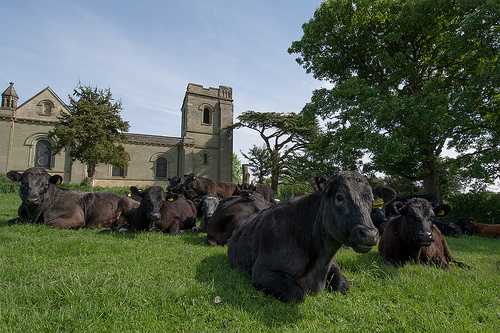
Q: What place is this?
A: It is a field.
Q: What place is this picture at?
A: It is at the field.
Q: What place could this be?
A: It is a field.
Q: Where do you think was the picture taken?
A: It was taken at the field.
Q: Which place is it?
A: It is a field.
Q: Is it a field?
A: Yes, it is a field.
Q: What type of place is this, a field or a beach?
A: It is a field.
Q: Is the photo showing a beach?
A: No, the picture is showing a field.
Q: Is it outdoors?
A: Yes, it is outdoors.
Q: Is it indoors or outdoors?
A: It is outdoors.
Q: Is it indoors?
A: No, it is outdoors.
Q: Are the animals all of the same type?
A: Yes, all the animals are cows.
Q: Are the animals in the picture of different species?
A: No, all the animals are cows.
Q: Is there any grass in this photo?
A: Yes, there is grass.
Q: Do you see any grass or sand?
A: Yes, there is grass.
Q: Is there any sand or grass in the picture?
A: Yes, there is grass.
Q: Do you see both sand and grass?
A: No, there is grass but no sand.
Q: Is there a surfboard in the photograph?
A: No, there are no surfboards.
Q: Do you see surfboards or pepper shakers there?
A: No, there are no surfboards or pepper shakers.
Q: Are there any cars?
A: No, there are no cars.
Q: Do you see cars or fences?
A: No, there are no cars or fences.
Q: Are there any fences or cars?
A: No, there are no cars or fences.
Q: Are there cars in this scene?
A: No, there are no cars.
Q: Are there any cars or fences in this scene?
A: No, there are no cars or fences.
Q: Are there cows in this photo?
A: Yes, there is a cow.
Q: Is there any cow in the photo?
A: Yes, there is a cow.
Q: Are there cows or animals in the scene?
A: Yes, there is a cow.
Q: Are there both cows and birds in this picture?
A: No, there is a cow but no birds.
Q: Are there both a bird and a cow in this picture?
A: No, there is a cow but no birds.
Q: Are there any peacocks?
A: No, there are no peacocks.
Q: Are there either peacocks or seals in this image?
A: No, there are no peacocks or seals.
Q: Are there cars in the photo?
A: No, there are no cars.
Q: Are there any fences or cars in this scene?
A: No, there are no cars or fences.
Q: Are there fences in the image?
A: No, there are no fences.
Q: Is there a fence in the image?
A: No, there are no fences.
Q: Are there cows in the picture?
A: Yes, there is a cow.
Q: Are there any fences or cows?
A: Yes, there is a cow.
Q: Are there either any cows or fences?
A: Yes, there is a cow.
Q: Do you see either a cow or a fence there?
A: Yes, there is a cow.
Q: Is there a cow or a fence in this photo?
A: Yes, there is a cow.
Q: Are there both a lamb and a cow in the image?
A: No, there is a cow but no lambs.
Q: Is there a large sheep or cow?
A: Yes, there is a large cow.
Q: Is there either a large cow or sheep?
A: Yes, there is a large cow.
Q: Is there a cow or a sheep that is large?
A: Yes, the cow is large.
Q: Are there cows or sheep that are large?
A: Yes, the cow is large.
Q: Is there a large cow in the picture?
A: Yes, there is a large cow.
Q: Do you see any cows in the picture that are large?
A: Yes, there is a cow that is large.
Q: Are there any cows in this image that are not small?
A: Yes, there is a large cow.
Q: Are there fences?
A: No, there are no fences.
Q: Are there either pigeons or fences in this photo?
A: No, there are no fences or pigeons.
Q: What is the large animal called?
A: The animal is a cow.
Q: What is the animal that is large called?
A: The animal is a cow.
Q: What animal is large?
A: The animal is a cow.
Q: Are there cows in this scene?
A: Yes, there is a cow.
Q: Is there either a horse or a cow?
A: Yes, there is a cow.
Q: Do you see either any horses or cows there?
A: Yes, there is a cow.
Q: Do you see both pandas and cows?
A: No, there is a cow but no pandas.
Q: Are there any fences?
A: No, there are no fences.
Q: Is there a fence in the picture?
A: No, there are no fences.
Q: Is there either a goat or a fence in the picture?
A: No, there are no fences or goats.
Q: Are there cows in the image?
A: Yes, there is a cow.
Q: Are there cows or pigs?
A: Yes, there is a cow.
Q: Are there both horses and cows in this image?
A: No, there is a cow but no horses.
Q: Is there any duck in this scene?
A: No, there are no ducks.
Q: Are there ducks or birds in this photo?
A: No, there are no ducks or birds.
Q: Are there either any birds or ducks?
A: No, there are no ducks or birds.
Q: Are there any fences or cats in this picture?
A: No, there are no fences or cats.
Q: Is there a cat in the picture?
A: No, there are no cats.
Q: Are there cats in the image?
A: No, there are no cats.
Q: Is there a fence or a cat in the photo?
A: No, there are no cats or fences.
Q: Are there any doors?
A: Yes, there is a door.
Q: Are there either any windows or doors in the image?
A: Yes, there is a door.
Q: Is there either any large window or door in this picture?
A: Yes, there is a large door.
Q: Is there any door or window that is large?
A: Yes, the door is large.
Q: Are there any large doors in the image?
A: Yes, there is a large door.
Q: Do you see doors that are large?
A: Yes, there is a door that is large.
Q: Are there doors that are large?
A: Yes, there is a door that is large.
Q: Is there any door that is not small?
A: Yes, there is a large door.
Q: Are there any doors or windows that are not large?
A: No, there is a door but it is large.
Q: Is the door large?
A: Yes, the door is large.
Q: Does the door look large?
A: Yes, the door is large.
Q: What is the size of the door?
A: The door is large.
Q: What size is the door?
A: The door is large.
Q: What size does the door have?
A: The door has large size.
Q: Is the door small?
A: No, the door is large.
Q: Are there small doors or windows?
A: No, there is a door but it is large.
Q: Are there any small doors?
A: No, there is a door but it is large.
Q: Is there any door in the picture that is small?
A: No, there is a door but it is large.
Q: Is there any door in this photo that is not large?
A: No, there is a door but it is large.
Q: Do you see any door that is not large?
A: No, there is a door but it is large.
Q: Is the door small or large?
A: The door is large.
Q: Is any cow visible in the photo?
A: Yes, there is a cow.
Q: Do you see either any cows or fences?
A: Yes, there is a cow.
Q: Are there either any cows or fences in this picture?
A: Yes, there is a cow.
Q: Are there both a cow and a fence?
A: No, there is a cow but no fences.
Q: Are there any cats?
A: No, there are no cats.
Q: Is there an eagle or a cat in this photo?
A: No, there are no cats or eagles.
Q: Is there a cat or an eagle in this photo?
A: No, there are no cats or eagles.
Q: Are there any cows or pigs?
A: Yes, there is a cow.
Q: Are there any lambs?
A: No, there are no lambs.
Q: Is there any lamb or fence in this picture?
A: No, there are no lambs or fences.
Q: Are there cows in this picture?
A: Yes, there are cows.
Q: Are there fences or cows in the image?
A: Yes, there are cows.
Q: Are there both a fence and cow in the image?
A: No, there are cows but no fences.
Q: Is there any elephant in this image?
A: No, there are no elephants.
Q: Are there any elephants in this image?
A: No, there are no elephants.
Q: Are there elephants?
A: No, there are no elephants.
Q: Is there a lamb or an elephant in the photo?
A: No, there are no elephants or lambs.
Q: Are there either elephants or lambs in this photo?
A: No, there are no elephants or lambs.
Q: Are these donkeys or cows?
A: These are cows.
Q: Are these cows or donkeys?
A: These are cows.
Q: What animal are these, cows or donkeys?
A: These are cows.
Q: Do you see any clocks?
A: No, there are no clocks.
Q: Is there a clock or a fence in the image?
A: No, there are no clocks or fences.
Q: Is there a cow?
A: Yes, there is a cow.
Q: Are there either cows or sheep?
A: Yes, there is a cow.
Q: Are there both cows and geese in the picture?
A: No, there is a cow but no geese.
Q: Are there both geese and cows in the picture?
A: No, there is a cow but no geese.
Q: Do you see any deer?
A: No, there are no deer.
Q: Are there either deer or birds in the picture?
A: No, there are no deer or birds.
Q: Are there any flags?
A: No, there are no flags.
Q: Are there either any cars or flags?
A: No, there are no flags or cars.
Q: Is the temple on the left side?
A: Yes, the temple is on the left of the image.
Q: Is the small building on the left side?
A: Yes, the temple is on the left of the image.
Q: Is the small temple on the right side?
A: No, the temple is on the left of the image.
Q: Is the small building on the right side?
A: No, the temple is on the left of the image.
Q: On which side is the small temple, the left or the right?
A: The temple is on the left of the image.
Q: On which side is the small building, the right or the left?
A: The temple is on the left of the image.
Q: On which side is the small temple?
A: The temple is on the left of the image.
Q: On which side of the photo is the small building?
A: The temple is on the left of the image.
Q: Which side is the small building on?
A: The temple is on the left of the image.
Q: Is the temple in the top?
A: Yes, the temple is in the top of the image.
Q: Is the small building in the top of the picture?
A: Yes, the temple is in the top of the image.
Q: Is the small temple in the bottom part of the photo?
A: No, the temple is in the top of the image.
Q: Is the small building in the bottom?
A: No, the temple is in the top of the image.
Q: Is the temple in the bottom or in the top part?
A: The temple is in the top of the image.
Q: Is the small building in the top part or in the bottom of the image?
A: The temple is in the top of the image.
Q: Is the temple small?
A: Yes, the temple is small.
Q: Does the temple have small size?
A: Yes, the temple is small.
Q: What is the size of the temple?
A: The temple is small.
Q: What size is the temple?
A: The temple is small.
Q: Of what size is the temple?
A: The temple is small.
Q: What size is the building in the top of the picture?
A: The temple is small.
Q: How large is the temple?
A: The temple is small.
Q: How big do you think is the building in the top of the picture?
A: The temple is small.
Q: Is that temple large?
A: No, the temple is small.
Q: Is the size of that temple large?
A: No, the temple is small.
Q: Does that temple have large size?
A: No, the temple is small.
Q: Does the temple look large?
A: No, the temple is small.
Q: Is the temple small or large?
A: The temple is small.